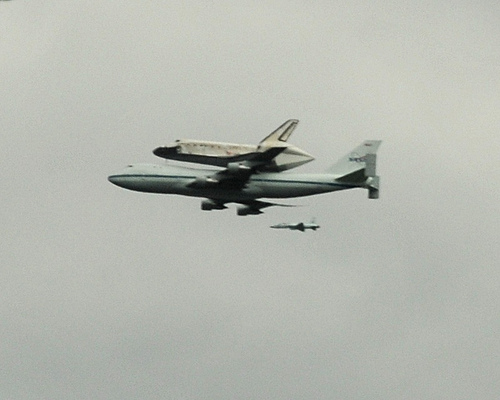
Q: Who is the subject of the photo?
A: The planes.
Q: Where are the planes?
A: In the air.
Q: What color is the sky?
A: Gray.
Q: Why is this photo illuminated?
A: Sunlight.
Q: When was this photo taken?
A: During the day.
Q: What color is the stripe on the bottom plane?
A: Blue.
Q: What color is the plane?
A: White.